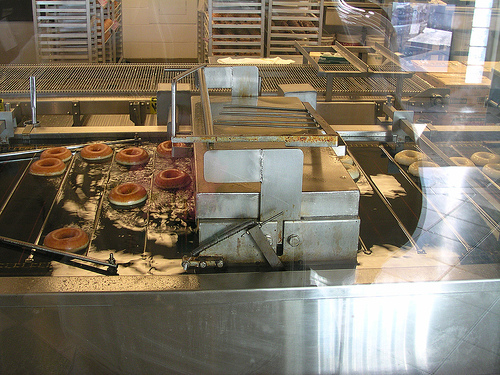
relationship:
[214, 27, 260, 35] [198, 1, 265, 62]
donuts in bakers rack